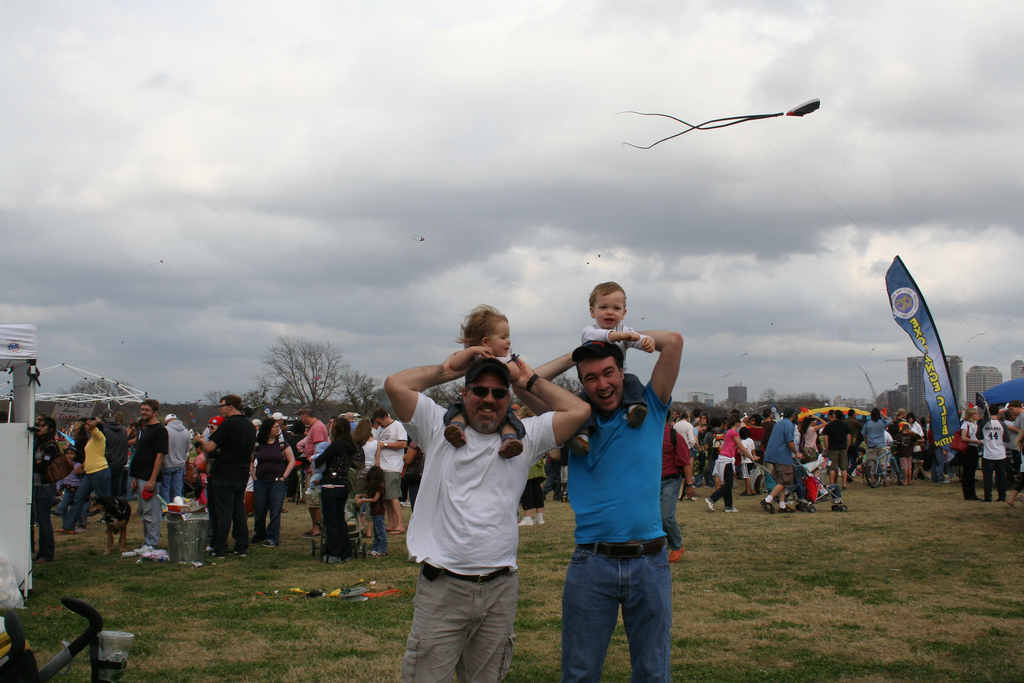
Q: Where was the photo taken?
A: In a park.